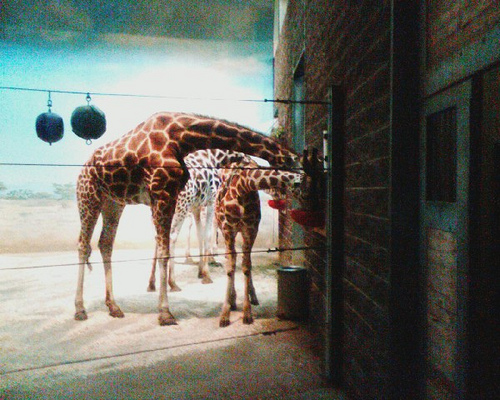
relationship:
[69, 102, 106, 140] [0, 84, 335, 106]
object hanging from line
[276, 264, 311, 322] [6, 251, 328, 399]
container sitting on ground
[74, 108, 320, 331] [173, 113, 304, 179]
giraffe has neck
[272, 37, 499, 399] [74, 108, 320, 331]
building next to giraffe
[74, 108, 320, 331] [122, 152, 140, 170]
giraffe has spots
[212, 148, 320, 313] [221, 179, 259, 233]
giraffe has spots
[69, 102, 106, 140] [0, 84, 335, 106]
container hanging from line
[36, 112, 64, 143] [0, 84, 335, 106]
container hanging from line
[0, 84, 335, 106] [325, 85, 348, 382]
line attached to post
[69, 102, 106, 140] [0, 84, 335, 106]
ball attached to line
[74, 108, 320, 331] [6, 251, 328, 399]
giraffe standing on dirt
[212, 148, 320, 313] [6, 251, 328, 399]
giraffe standing on dirt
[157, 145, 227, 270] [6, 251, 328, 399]
giraffe standing on dirt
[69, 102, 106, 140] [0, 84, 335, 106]
weight hanging from line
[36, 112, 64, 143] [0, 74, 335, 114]
weight hanging from line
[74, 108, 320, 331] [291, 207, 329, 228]
giraffe eating from bucket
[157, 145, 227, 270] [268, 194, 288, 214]
giraffe eating from bucket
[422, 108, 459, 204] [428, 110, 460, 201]
window has bars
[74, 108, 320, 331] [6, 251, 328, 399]
giraffe standing on ground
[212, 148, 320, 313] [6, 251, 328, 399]
giraffe standing on ground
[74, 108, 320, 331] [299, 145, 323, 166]
giraffe has horns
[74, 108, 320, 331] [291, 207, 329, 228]
giraffe eating food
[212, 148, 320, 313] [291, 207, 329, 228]
giraffe eating food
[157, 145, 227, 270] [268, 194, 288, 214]
giraffe eating food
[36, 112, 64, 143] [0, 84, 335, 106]
container hangs from line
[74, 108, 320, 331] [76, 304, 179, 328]
giraffe has feet